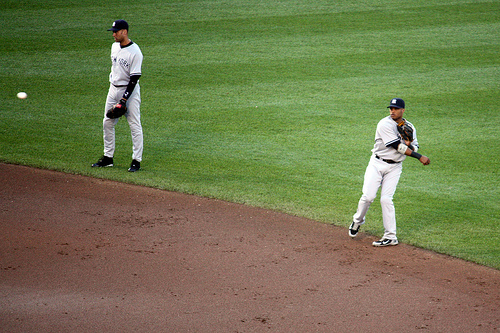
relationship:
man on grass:
[91, 19, 143, 173] [0, 2, 499, 270]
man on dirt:
[349, 99, 427, 248] [2, 161, 497, 332]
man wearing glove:
[91, 19, 143, 173] [107, 105, 127, 120]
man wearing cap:
[91, 19, 143, 173] [107, 19, 128, 33]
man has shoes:
[91, 19, 143, 173] [91, 156, 140, 173]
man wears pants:
[91, 19, 143, 173] [103, 84, 143, 165]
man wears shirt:
[91, 19, 143, 173] [110, 42, 143, 99]